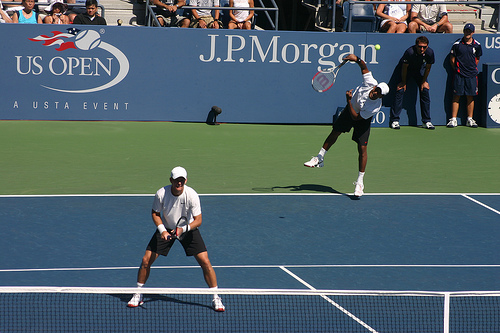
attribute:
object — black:
[204, 106, 223, 126]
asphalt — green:
[1, 121, 499, 194]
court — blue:
[0, 194, 499, 333]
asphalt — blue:
[3, 195, 500, 332]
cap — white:
[169, 166, 188, 180]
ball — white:
[74, 29, 100, 54]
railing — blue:
[142, 1, 280, 28]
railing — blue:
[292, 1, 496, 32]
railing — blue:
[0, 3, 105, 26]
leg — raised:
[302, 106, 353, 170]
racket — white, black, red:
[310, 59, 348, 94]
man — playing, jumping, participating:
[304, 54, 390, 199]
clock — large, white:
[487, 92, 500, 127]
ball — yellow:
[374, 43, 380, 52]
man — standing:
[390, 36, 436, 130]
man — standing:
[446, 25, 486, 129]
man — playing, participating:
[127, 166, 226, 313]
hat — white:
[372, 82, 389, 97]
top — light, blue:
[18, 10, 38, 24]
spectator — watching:
[45, 3, 69, 28]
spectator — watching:
[74, 1, 106, 26]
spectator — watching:
[154, 2, 194, 30]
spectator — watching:
[190, 2, 222, 31]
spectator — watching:
[229, 1, 258, 31]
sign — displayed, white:
[200, 33, 380, 75]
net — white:
[1, 286, 499, 332]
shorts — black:
[332, 106, 371, 146]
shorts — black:
[147, 226, 207, 257]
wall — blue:
[0, 25, 499, 126]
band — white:
[157, 225, 166, 235]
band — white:
[180, 225, 191, 233]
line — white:
[279, 263, 377, 332]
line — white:
[463, 194, 500, 218]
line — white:
[4, 264, 500, 274]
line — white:
[1, 194, 500, 198]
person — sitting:
[410, 1, 452, 35]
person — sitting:
[375, 1, 410, 36]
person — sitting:
[227, 2, 254, 32]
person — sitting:
[188, 1, 223, 30]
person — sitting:
[146, 2, 191, 26]